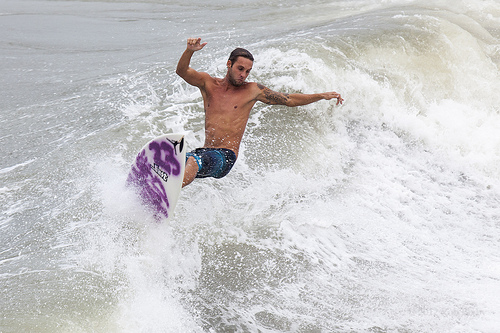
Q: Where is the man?
A: The ocean.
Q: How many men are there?
A: 1.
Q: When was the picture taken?
A: Daytime.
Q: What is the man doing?
A: Surfing.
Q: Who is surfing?
A: The man.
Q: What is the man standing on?
A: A surfboard.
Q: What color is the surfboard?
A: White and purple.